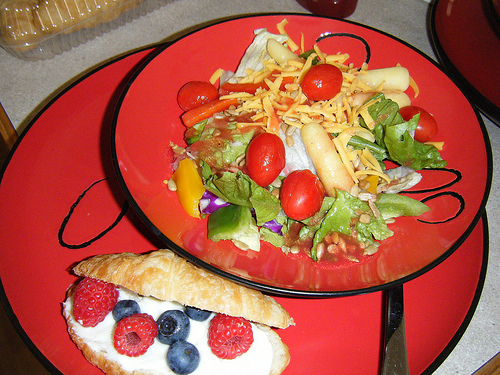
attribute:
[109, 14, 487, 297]
plate — red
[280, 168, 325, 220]
tomato — red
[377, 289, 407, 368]
handle — utensil handle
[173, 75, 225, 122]
tomato — red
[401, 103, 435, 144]
tomato — red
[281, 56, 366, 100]
tomato — red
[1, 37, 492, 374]
plate — red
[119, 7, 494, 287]
salad bowl — red, black